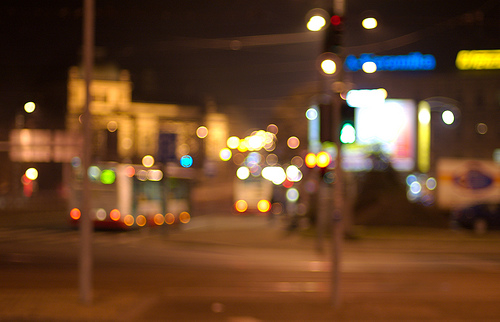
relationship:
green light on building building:
[342, 105, 359, 149] [327, 2, 498, 228]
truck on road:
[432, 156, 499, 233] [1, 215, 499, 319]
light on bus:
[110, 210, 189, 224] [72, 159, 199, 231]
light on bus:
[130, 211, 149, 228] [72, 159, 199, 231]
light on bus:
[101, 203, 123, 224] [72, 159, 199, 231]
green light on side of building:
[342, 105, 359, 149] [2, 2, 499, 212]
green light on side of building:
[327, 98, 366, 163] [2, 2, 499, 212]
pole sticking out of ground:
[78, 0, 98, 303] [162, 212, 346, 297]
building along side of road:
[8, 47, 231, 164] [1, 197, 498, 287]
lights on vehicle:
[233, 200, 279, 215] [227, 172, 298, 214]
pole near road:
[77, 0, 90, 303] [1, 215, 499, 319]